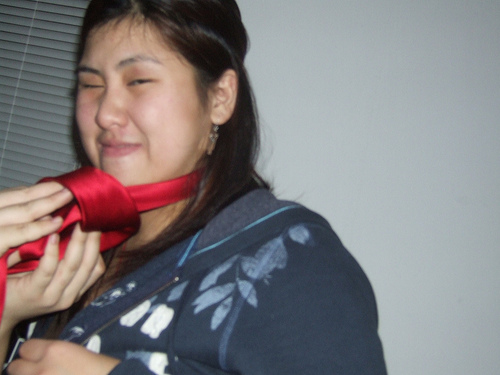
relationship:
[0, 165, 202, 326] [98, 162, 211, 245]
necktie around neck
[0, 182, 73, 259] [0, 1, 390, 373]
hand tying on an asian woman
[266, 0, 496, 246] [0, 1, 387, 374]
wall behind asian woman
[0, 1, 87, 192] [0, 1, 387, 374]
blind behind asian woman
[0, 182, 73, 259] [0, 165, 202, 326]
hand holding necktie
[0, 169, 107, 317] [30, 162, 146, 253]
person tying tie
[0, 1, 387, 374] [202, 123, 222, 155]
asian woman wearing ear ring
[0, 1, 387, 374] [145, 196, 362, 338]
asian woman wearing jacket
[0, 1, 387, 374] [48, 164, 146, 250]
asian woman wearing tie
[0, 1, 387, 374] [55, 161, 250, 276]
asian woman wearing tie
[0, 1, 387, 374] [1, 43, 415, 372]
asian woman wearing jacket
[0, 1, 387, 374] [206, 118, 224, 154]
asian woman wearing ear ring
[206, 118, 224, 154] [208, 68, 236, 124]
ear ring hanging from ear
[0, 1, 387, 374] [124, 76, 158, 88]
asian woman has eyes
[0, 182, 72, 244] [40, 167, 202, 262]
hand looping necktie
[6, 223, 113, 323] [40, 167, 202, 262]
hand looping necktie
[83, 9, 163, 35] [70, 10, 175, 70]
bangs on forehead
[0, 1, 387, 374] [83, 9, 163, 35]
asian woman has bangs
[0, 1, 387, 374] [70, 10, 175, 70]
asian woman has forehead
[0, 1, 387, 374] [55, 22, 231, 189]
asian woman has face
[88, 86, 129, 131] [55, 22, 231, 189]
nose on face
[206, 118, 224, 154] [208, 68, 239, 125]
ear ring in ear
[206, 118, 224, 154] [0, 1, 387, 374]
ear ring on asian woman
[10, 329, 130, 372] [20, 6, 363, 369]
hand on woman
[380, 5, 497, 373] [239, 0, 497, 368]
wall next to woman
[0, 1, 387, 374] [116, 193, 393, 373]
asian woman wearing jacket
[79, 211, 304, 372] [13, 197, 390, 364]
illustration on jacket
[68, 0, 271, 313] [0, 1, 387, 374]
hair on asian woman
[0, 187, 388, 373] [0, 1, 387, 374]
blue jacket on asian woman